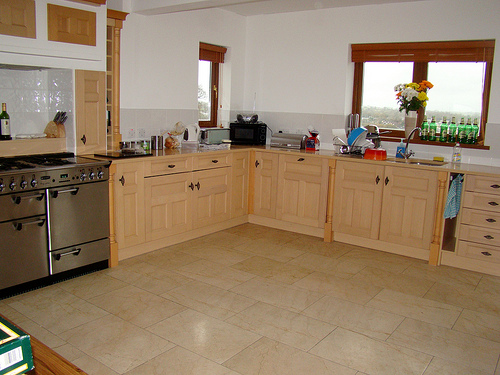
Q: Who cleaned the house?
A: The owner.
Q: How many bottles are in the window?
A: 7.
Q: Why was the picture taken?
A: To show the kitchen.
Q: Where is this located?
A: The kitchen.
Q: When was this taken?
A: During the day.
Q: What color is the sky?
A: Grey.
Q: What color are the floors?
A: White.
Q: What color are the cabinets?
A: Brown.